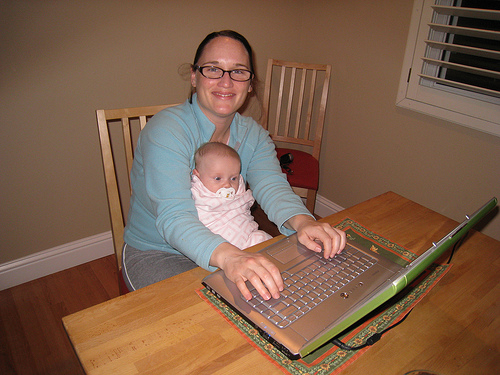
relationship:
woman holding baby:
[111, 22, 344, 298] [173, 141, 272, 260]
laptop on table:
[195, 187, 500, 359] [60, 185, 500, 374]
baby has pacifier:
[173, 141, 272, 260] [212, 185, 238, 202]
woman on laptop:
[111, 22, 344, 298] [195, 187, 500, 359]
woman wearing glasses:
[111, 22, 344, 298] [191, 62, 259, 84]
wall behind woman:
[1, 0, 499, 273] [111, 22, 344, 298]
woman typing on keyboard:
[111, 22, 344, 298] [226, 230, 381, 333]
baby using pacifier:
[173, 141, 272, 260] [212, 185, 238, 202]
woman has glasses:
[111, 22, 344, 298] [191, 62, 259, 84]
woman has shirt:
[111, 22, 344, 298] [119, 93, 327, 263]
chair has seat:
[245, 55, 339, 225] [253, 144, 326, 192]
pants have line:
[112, 234, 210, 300] [118, 238, 141, 302]